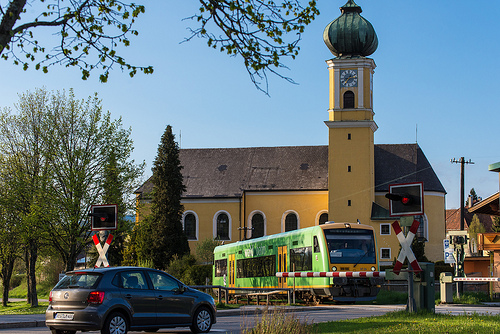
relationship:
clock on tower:
[331, 67, 371, 86] [320, 1, 382, 206]